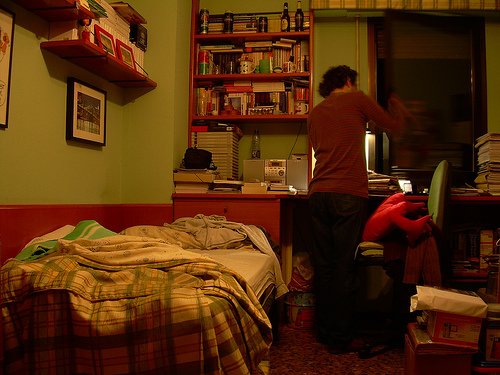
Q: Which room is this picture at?
A: It is at the bedroom.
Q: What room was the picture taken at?
A: It was taken at the bedroom.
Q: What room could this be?
A: It is a bedroom.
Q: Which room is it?
A: It is a bedroom.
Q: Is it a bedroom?
A: Yes, it is a bedroom.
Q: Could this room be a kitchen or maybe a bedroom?
A: It is a bedroom.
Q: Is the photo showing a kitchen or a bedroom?
A: It is showing a bedroom.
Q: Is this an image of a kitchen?
A: No, the picture is showing a bedroom.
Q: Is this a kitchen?
A: No, it is a bedroom.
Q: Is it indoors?
A: Yes, it is indoors.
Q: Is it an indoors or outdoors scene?
A: It is indoors.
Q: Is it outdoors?
A: No, it is indoors.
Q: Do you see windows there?
A: Yes, there is a window.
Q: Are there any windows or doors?
A: Yes, there is a window.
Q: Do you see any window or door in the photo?
A: Yes, there is a window.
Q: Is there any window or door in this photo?
A: Yes, there is a window.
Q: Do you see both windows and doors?
A: No, there is a window but no doors.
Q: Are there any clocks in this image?
A: No, there are no clocks.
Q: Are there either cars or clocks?
A: No, there are no clocks or cars.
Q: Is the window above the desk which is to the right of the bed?
A: Yes, the window is above the desk.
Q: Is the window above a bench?
A: No, the window is above the desk.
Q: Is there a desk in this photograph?
A: Yes, there is a desk.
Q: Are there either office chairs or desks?
A: Yes, there is a desk.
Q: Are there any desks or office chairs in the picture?
A: Yes, there is a desk.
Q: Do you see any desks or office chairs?
A: Yes, there is a desk.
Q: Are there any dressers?
A: No, there are no dressers.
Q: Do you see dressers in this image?
A: No, there are no dressers.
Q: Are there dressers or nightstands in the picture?
A: No, there are no dressers or nightstands.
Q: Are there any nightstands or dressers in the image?
A: No, there are no dressers or nightstands.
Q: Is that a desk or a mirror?
A: That is a desk.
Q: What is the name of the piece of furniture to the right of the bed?
A: The piece of furniture is a desk.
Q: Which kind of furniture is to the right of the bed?
A: The piece of furniture is a desk.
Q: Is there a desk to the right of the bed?
A: Yes, there is a desk to the right of the bed.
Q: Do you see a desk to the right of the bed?
A: Yes, there is a desk to the right of the bed.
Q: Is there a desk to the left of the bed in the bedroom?
A: No, the desk is to the right of the bed.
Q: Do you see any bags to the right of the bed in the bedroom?
A: No, there is a desk to the right of the bed.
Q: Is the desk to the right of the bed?
A: Yes, the desk is to the right of the bed.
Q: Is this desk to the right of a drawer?
A: No, the desk is to the right of the bed.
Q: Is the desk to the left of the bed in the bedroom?
A: No, the desk is to the right of the bed.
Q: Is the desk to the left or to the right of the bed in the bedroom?
A: The desk is to the right of the bed.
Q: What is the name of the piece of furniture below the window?
A: The piece of furniture is a desk.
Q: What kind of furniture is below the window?
A: The piece of furniture is a desk.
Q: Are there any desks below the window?
A: Yes, there is a desk below the window.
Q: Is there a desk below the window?
A: Yes, there is a desk below the window.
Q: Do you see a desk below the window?
A: Yes, there is a desk below the window.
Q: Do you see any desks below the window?
A: Yes, there is a desk below the window.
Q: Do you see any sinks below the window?
A: No, there is a desk below the window.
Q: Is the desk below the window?
A: Yes, the desk is below the window.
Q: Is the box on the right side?
A: Yes, the box is on the right of the image.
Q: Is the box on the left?
A: No, the box is on the right of the image.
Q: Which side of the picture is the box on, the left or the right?
A: The box is on the right of the image.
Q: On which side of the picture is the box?
A: The box is on the right of the image.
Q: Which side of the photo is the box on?
A: The box is on the right of the image.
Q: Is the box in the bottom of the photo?
A: Yes, the box is in the bottom of the image.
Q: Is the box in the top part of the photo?
A: No, the box is in the bottom of the image.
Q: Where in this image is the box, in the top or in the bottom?
A: The box is in the bottom of the image.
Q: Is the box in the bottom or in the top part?
A: The box is in the bottom of the image.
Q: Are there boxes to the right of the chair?
A: Yes, there is a box to the right of the chair.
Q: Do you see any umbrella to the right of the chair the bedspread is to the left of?
A: No, there is a box to the right of the chair.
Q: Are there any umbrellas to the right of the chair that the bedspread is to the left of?
A: No, there is a box to the right of the chair.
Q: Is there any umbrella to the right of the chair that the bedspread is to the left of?
A: No, there is a box to the right of the chair.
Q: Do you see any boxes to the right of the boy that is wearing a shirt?
A: Yes, there is a box to the right of the boy.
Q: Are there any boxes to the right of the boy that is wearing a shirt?
A: Yes, there is a box to the right of the boy.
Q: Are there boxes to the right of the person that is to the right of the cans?
A: Yes, there is a box to the right of the boy.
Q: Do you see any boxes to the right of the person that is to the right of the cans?
A: Yes, there is a box to the right of the boy.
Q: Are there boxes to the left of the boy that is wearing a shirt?
A: No, the box is to the right of the boy.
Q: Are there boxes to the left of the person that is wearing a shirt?
A: No, the box is to the right of the boy.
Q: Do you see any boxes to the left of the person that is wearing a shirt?
A: No, the box is to the right of the boy.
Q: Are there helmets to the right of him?
A: No, there is a box to the right of the boy.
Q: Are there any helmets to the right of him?
A: No, there is a box to the right of the boy.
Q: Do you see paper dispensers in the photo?
A: No, there are no paper dispensers.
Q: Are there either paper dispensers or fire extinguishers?
A: No, there are no paper dispensers or fire extinguishers.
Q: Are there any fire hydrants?
A: No, there are no fire hydrants.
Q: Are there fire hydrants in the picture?
A: No, there are no fire hydrants.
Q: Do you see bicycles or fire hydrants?
A: No, there are no fire hydrants or bicycles.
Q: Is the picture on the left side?
A: Yes, the picture is on the left of the image.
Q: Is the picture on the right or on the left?
A: The picture is on the left of the image.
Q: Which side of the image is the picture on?
A: The picture is on the left of the image.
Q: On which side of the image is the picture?
A: The picture is on the left of the image.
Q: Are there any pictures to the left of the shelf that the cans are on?
A: Yes, there is a picture to the left of the shelf.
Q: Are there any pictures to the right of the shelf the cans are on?
A: No, the picture is to the left of the shelf.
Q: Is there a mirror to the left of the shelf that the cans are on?
A: No, there is a picture to the left of the shelf.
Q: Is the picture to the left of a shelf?
A: Yes, the picture is to the left of a shelf.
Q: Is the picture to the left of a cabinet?
A: No, the picture is to the left of a shelf.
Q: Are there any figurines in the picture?
A: No, there are no figurines.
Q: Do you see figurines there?
A: No, there are no figurines.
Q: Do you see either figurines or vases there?
A: No, there are no figurines or vases.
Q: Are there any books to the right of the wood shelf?
A: Yes, there is a book to the right of the shelf.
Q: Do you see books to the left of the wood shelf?
A: No, the book is to the right of the shelf.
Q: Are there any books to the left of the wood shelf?
A: No, the book is to the right of the shelf.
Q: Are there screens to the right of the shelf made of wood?
A: No, there is a book to the right of the shelf.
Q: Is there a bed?
A: Yes, there is a bed.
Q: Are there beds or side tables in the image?
A: Yes, there is a bed.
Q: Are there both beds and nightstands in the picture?
A: No, there is a bed but no nightstands.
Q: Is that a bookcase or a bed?
A: That is a bed.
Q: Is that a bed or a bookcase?
A: That is a bed.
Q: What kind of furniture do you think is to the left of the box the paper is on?
A: The piece of furniture is a bed.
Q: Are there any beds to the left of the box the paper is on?
A: Yes, there is a bed to the left of the box.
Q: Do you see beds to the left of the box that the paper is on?
A: Yes, there is a bed to the left of the box.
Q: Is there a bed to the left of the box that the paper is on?
A: Yes, there is a bed to the left of the box.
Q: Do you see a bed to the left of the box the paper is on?
A: Yes, there is a bed to the left of the box.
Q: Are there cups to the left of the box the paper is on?
A: No, there is a bed to the left of the box.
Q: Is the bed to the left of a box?
A: Yes, the bed is to the left of a box.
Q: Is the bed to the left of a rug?
A: No, the bed is to the left of a box.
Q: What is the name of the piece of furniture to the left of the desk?
A: The piece of furniture is a bed.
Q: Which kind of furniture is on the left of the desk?
A: The piece of furniture is a bed.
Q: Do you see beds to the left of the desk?
A: Yes, there is a bed to the left of the desk.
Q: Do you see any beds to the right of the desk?
A: No, the bed is to the left of the desk.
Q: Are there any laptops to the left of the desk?
A: No, there is a bed to the left of the desk.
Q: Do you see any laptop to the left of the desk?
A: No, there is a bed to the left of the desk.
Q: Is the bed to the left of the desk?
A: Yes, the bed is to the left of the desk.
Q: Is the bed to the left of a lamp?
A: No, the bed is to the left of the desk.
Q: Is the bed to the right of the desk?
A: No, the bed is to the left of the desk.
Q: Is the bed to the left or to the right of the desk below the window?
A: The bed is to the left of the desk.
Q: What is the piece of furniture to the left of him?
A: The piece of furniture is a bed.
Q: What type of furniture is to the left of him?
A: The piece of furniture is a bed.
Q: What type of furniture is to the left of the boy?
A: The piece of furniture is a bed.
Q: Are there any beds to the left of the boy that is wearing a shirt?
A: Yes, there is a bed to the left of the boy.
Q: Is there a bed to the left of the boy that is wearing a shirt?
A: Yes, there is a bed to the left of the boy.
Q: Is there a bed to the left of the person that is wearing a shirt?
A: Yes, there is a bed to the left of the boy.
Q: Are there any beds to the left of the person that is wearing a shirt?
A: Yes, there is a bed to the left of the boy.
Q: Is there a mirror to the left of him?
A: No, there is a bed to the left of the boy.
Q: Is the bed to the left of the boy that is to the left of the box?
A: Yes, the bed is to the left of the boy.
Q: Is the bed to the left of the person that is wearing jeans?
A: Yes, the bed is to the left of the boy.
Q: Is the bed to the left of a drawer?
A: No, the bed is to the left of the boy.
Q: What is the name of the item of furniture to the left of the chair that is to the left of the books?
A: The piece of furniture is a bed.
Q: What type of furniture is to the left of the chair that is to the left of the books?
A: The piece of furniture is a bed.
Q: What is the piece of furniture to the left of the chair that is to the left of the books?
A: The piece of furniture is a bed.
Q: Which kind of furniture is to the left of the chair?
A: The piece of furniture is a bed.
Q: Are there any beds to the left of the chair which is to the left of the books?
A: Yes, there is a bed to the left of the chair.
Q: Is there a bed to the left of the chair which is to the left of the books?
A: Yes, there is a bed to the left of the chair.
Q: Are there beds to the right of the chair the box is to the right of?
A: No, the bed is to the left of the chair.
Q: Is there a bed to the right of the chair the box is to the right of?
A: No, the bed is to the left of the chair.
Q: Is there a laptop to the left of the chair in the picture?
A: No, there is a bed to the left of the chair.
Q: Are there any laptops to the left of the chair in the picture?
A: No, there is a bed to the left of the chair.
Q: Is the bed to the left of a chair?
A: Yes, the bed is to the left of a chair.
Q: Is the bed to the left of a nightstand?
A: No, the bed is to the left of a chair.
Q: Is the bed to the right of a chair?
A: No, the bed is to the left of a chair.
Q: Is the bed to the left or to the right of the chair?
A: The bed is to the left of the chair.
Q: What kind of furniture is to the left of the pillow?
A: The piece of furniture is a bed.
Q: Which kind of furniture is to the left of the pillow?
A: The piece of furniture is a bed.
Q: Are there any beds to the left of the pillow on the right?
A: Yes, there is a bed to the left of the pillow.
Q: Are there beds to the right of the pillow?
A: No, the bed is to the left of the pillow.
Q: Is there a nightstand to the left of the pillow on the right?
A: No, there is a bed to the left of the pillow.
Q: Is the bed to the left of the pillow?
A: Yes, the bed is to the left of the pillow.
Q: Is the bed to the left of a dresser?
A: No, the bed is to the left of the pillow.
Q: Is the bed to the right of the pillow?
A: No, the bed is to the left of the pillow.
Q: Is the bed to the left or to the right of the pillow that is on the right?
A: The bed is to the left of the pillow.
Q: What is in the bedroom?
A: The bed is in the bedroom.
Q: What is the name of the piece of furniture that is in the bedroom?
A: The piece of furniture is a bed.